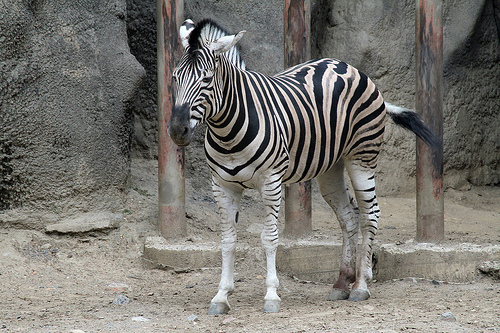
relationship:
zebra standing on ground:
[170, 13, 444, 313] [27, 264, 250, 330]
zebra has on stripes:
[170, 13, 444, 313] [260, 73, 349, 162]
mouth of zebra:
[174, 133, 193, 144] [170, 13, 444, 313]